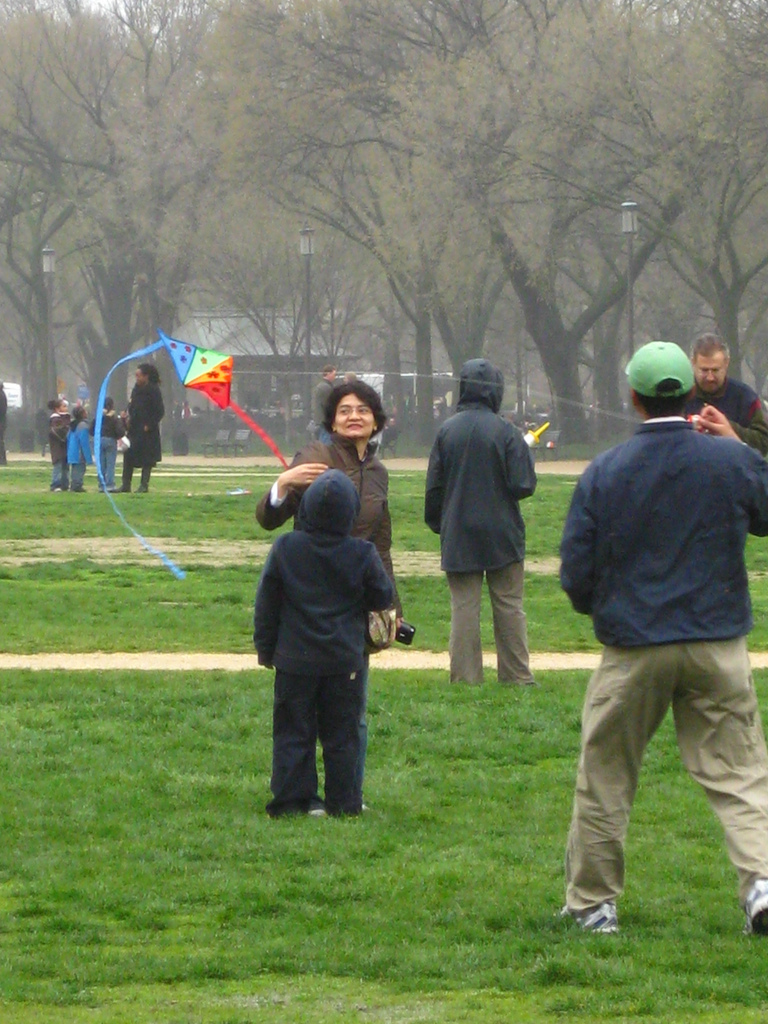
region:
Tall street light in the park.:
[292, 183, 323, 446]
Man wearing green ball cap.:
[613, 319, 700, 422]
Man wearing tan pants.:
[536, 633, 746, 896]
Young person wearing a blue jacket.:
[240, 465, 401, 686]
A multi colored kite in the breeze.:
[136, 320, 275, 414]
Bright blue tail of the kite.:
[91, 322, 168, 599]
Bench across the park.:
[202, 413, 252, 465]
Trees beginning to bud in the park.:
[330, 18, 610, 200]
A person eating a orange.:
[428, 841, 483, 948]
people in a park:
[31, 29, 763, 1004]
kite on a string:
[79, 315, 718, 590]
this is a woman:
[217, 361, 430, 595]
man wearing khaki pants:
[564, 625, 764, 948]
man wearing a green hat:
[603, 328, 712, 420]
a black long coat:
[114, 384, 172, 473]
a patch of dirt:
[28, 489, 584, 605]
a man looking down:
[676, 309, 758, 446]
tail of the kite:
[39, 339, 204, 606]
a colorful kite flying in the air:
[91, 327, 287, 579]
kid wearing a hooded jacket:
[255, 470, 394, 814]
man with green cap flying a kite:
[558, 337, 764, 938]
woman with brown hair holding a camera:
[260, 380, 416, 649]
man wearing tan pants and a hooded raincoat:
[419, 360, 542, 682]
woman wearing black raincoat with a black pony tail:
[111, 363, 165, 488]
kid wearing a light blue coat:
[65, 406, 92, 491]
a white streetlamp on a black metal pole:
[296, 220, 314, 441]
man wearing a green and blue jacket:
[673, 332, 764, 450]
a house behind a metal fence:
[175, 312, 369, 455]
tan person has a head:
[459, 360, 505, 413]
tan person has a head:
[622, 343, 697, 417]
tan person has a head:
[686, 337, 730, 387]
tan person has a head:
[136, 364, 157, 383]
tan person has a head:
[101, 395, 116, 413]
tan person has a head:
[72, 404, 88, 428]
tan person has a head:
[322, 366, 335, 381]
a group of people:
[13, 262, 764, 983]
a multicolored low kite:
[139, 303, 288, 465]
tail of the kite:
[71, 329, 204, 551]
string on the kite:
[203, 347, 630, 440]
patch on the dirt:
[19, 495, 259, 575]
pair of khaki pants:
[574, 607, 767, 917]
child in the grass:
[203, 434, 438, 846]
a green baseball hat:
[615, 341, 696, 402]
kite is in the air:
[130, 317, 251, 447]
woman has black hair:
[297, 360, 399, 428]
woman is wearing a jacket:
[278, 431, 384, 519]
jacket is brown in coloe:
[301, 428, 411, 553]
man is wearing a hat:
[583, 343, 694, 415]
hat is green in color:
[617, 331, 702, 405]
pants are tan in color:
[571, 629, 758, 953]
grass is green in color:
[48, 633, 645, 1019]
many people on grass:
[66, 281, 752, 647]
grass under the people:
[36, 850, 252, 959]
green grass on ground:
[59, 812, 247, 927]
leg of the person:
[492, 762, 676, 954]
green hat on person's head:
[574, 308, 711, 450]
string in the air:
[268, 347, 647, 434]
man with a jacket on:
[498, 350, 753, 664]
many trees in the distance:
[54, 50, 690, 243]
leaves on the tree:
[126, 42, 570, 208]